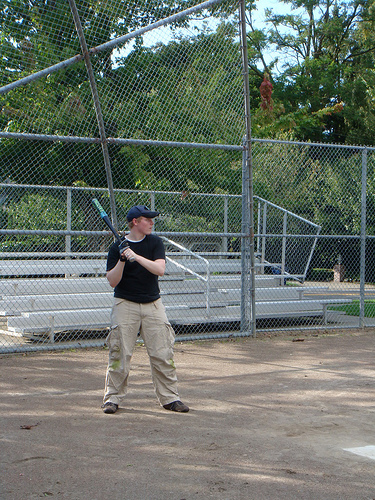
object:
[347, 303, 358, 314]
green grass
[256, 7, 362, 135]
green trees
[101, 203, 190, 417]
baseball player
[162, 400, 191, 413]
brown shoes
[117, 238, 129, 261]
batting glove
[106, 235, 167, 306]
shirt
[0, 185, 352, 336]
bleachers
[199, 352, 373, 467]
field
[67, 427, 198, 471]
shadow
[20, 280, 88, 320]
steps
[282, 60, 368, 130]
trees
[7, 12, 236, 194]
fence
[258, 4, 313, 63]
sky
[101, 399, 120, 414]
shoe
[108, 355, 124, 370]
stain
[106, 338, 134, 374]
knee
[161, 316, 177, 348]
pocket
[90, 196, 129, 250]
base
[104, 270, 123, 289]
elbow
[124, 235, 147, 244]
collar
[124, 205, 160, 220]
cap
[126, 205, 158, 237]
head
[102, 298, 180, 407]
cargo pants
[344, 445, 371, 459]
home plate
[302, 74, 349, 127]
foliage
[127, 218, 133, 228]
hair